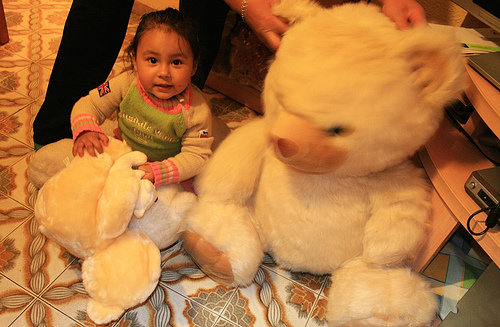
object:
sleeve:
[70, 74, 122, 142]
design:
[95, 80, 112, 98]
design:
[198, 128, 213, 139]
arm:
[138, 114, 216, 188]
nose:
[155, 65, 173, 79]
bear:
[33, 134, 163, 326]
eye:
[327, 124, 345, 136]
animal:
[181, 0, 469, 326]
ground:
[426, 239, 482, 314]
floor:
[1, 0, 491, 325]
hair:
[122, 6, 204, 75]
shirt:
[69, 68, 215, 187]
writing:
[146, 126, 154, 132]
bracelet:
[238, 0, 249, 19]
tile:
[155, 263, 282, 325]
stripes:
[149, 159, 179, 187]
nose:
[276, 136, 302, 159]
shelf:
[404, 60, 499, 281]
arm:
[70, 74, 129, 157]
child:
[70, 6, 213, 189]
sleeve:
[145, 105, 216, 188]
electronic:
[463, 163, 499, 228]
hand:
[240, 0, 291, 51]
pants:
[33, 0, 233, 146]